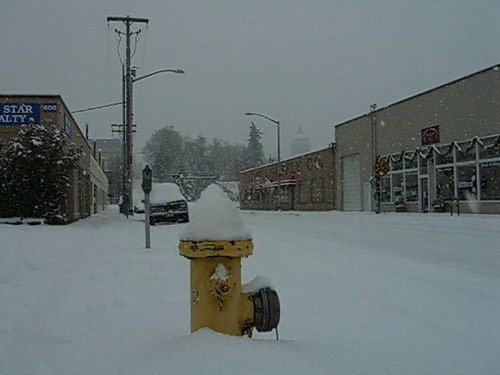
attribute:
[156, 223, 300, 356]
hydrant — on curb, yellow, snow-covered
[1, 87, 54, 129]
sign — blue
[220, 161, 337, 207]
building — brick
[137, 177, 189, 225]
truck — parked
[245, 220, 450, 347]
street — snow-covered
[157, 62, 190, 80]
lamp — tall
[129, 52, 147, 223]
pole — wooden, tall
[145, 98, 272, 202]
trees — in background, in distance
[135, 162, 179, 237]
meter — on curb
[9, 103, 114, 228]
building — foggy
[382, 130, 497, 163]
garland — green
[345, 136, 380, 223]
door — white